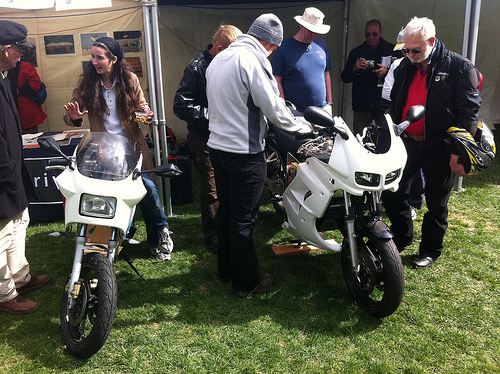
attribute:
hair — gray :
[398, 11, 438, 59]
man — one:
[384, 5, 498, 269]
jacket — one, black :
[398, 57, 483, 152]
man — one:
[384, 6, 474, 277]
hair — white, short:
[400, 13, 437, 43]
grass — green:
[1, 139, 484, 372]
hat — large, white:
[292, 5, 331, 36]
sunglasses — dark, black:
[400, 40, 426, 56]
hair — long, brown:
[69, 35, 141, 122]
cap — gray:
[245, 11, 285, 48]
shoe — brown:
[1, 294, 41, 314]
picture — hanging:
[30, 30, 86, 64]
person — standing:
[67, 30, 202, 222]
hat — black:
[3, 14, 52, 54]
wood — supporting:
[261, 231, 323, 252]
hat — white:
[287, 5, 338, 44]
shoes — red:
[5, 267, 45, 308]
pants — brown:
[168, 147, 252, 302]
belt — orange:
[396, 115, 459, 172]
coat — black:
[386, 60, 498, 162]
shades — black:
[389, 32, 435, 51]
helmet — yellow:
[422, 115, 494, 166]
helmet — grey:
[443, 117, 495, 185]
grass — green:
[165, 272, 313, 370]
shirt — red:
[392, 65, 440, 147]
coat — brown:
[122, 77, 179, 156]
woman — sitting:
[54, 41, 162, 161]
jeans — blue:
[117, 166, 189, 248]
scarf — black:
[84, 63, 149, 103]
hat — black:
[0, 25, 54, 97]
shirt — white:
[85, 99, 142, 144]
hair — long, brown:
[95, 32, 141, 84]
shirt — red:
[386, 57, 440, 133]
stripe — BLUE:
[245, 97, 262, 152]